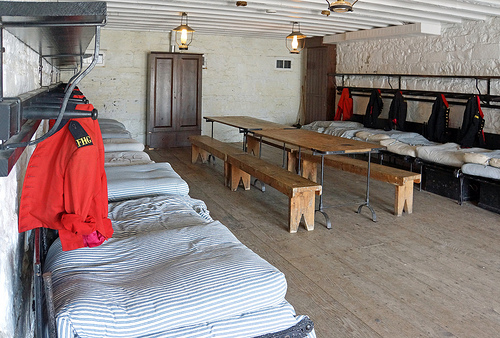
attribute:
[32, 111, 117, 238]
jacket — red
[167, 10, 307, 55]
lights — style, lantern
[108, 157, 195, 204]
bed — blue 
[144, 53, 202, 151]
cabinet — tall, brown, wooden cabinet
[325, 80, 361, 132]
coat — red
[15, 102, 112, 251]
jacket — red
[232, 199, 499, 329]
floor — wood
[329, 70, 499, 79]
bars — long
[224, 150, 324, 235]
bench — simple, hardwood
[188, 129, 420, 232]
benches — wooden, brown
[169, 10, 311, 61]
fixtures — light fixtures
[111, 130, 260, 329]
beds — row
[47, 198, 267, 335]
mattress — white striped, blue 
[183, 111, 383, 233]
table — long, hardwood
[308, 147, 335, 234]
leg — metal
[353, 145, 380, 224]
leg — metal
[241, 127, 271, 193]
leg — metal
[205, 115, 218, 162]
leg — metal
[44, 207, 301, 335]
bed — blue, unmade, striped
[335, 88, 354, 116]
jacket — red, hanging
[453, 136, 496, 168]
bed — unmade, blue striped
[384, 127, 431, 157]
bed — blue striped, unmade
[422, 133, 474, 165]
bed — blue striped, unmade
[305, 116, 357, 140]
bed — blue striped, unmade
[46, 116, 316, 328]
mattress — folded, bunk, style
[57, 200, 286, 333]
sheets — white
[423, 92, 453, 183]
jacket — red, black, soldier's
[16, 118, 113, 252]
jacket — red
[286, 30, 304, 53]
lamp — old, kerosine style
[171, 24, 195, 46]
lamp — old, kerosine style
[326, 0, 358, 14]
lamp — old, kerosine style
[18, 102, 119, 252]
jacket — Red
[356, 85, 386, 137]
jacket — red, black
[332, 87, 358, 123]
red jacket — soldier's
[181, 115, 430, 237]
benches — wooden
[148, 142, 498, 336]
boards — unfinished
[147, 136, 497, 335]
floor — plain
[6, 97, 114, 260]
jacket — red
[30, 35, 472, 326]
quarters — sleeping, soldier's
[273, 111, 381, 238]
table — wooden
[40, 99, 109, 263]
jacket — red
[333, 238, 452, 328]
floor — wood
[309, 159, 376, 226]
legs — metal